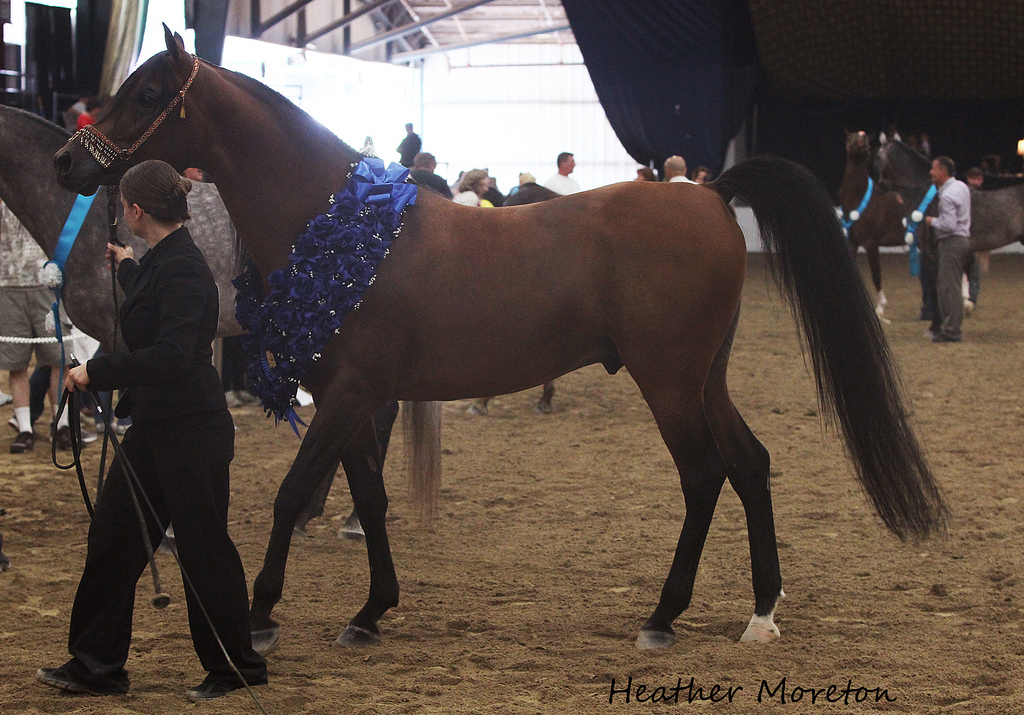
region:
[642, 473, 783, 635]
back legs of the horse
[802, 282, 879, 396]
the tail is black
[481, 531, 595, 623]
the sand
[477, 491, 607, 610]
the sand is brown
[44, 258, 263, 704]
a person walking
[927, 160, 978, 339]
a person standing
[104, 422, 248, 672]
the pants are black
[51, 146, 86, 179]
nostril of the horse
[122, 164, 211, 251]
Person has dark hair.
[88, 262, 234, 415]
Person wearing black jacket.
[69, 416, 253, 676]
Person wearing black pants.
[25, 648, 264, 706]
Person wearing black shoes.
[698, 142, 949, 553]
Horse has long black tail.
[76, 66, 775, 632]
Brown horse walking next to person.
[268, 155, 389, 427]
Blue sash around horse.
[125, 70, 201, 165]
Brown strap on horse's head.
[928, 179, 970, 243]
Person wearing long sleeve shirt.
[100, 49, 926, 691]
large brown horse led by woman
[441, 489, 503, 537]
brown dirt on inside pen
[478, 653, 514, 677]
brown dirt on inside pen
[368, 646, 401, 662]
brown dirt on inside pen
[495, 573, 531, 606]
brown dirt on inside pen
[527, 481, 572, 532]
brown dirt on inside pen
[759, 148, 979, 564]
black tail of horse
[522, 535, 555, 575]
brown dirt on inside pen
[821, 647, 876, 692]
brown dirt on inside pen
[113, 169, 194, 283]
the head of a woman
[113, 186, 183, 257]
the ear of a woman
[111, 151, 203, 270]
the hair of a woman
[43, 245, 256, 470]
the arm of a woman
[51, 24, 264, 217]
the head of a horse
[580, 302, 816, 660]
the legs of a horse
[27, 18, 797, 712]
a woman walking a horse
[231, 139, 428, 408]
A blue necklace around the horse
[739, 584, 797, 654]
The white hoof of a horse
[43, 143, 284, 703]
A woman wearing all black Clothing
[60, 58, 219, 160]
The bridle on the horses head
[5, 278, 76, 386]
A pair of shorts on a man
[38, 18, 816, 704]
A brown horse walking with the lady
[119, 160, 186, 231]
person is walking outside